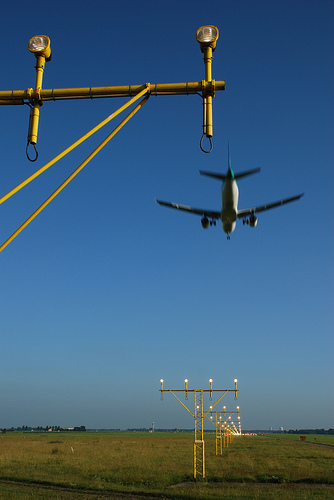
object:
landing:
[227, 436, 334, 484]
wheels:
[214, 221, 216, 226]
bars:
[159, 389, 240, 392]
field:
[0, 429, 334, 499]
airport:
[0, 425, 332, 499]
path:
[0, 479, 334, 499]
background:
[0, 425, 334, 433]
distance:
[0, 415, 334, 438]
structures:
[279, 427, 283, 431]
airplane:
[156, 143, 305, 241]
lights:
[160, 379, 163, 382]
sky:
[0, 0, 334, 427]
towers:
[0, 25, 224, 253]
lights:
[30, 37, 48, 51]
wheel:
[242, 219, 244, 224]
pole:
[170, 390, 194, 417]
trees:
[300, 430, 303, 434]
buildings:
[48, 428, 52, 432]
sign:
[300, 436, 306, 440]